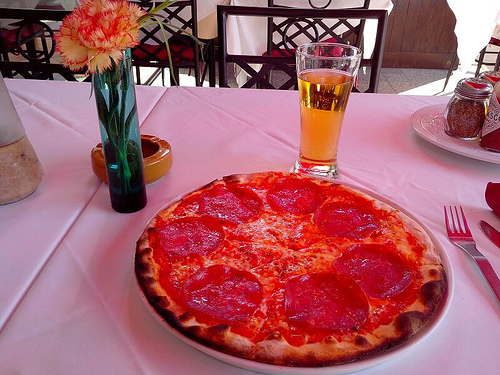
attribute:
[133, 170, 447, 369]
pizza — sliced, pepperoni, round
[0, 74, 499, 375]
table — pictured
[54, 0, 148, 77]
flowers — yellow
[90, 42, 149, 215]
vase — glass, green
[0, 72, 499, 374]
tablecloth — white, wrinkled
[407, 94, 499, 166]
plate — white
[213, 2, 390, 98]
chair — metal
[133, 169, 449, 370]
crust — burnt, well done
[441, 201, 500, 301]
fork — metal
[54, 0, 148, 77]
petals — pink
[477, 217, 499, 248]
knife — metal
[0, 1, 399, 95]
chairs — pictured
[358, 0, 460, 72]
wall — brown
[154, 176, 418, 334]
pepperoni — large, extraordinary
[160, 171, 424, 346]
cheese — melted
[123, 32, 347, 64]
cushions — red